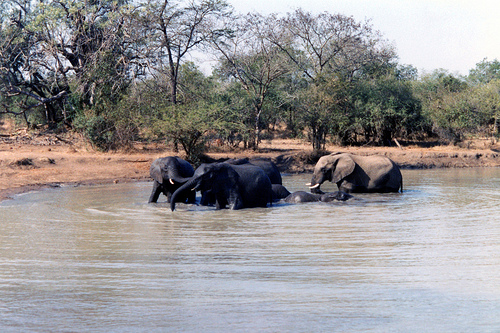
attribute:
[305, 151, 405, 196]
elephant — gray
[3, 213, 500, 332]
water — murky, murk, gray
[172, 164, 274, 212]
elephant — gray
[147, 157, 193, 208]
elephant — gray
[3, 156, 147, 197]
ground — brown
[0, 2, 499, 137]
trees — green